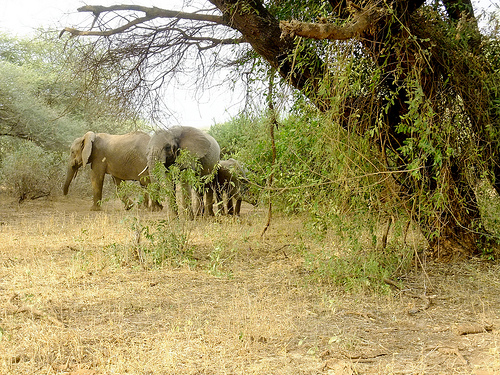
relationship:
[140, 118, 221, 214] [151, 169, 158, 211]
elephant has trunk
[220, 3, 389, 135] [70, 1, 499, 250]
branch of tree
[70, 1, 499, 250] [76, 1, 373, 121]
tree with branches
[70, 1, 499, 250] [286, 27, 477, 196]
tree with leaves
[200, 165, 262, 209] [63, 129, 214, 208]
elephant next to other elephants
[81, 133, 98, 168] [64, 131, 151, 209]
ear of elephant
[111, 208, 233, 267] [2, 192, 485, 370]
stick on ground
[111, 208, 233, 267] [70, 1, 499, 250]
stick by tree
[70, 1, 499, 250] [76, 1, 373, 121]
tree has branches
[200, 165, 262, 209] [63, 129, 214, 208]
elephant with other elephants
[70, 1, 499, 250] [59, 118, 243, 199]
tree near elephants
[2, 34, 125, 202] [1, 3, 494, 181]
tree in background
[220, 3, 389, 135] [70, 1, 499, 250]
branch hanging from tree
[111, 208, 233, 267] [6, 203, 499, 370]
stick laying on grass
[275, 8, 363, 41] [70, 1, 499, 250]
branch hanging from tree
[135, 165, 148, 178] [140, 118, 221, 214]
tusk on elephant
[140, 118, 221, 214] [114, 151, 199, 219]
elephant eating from shrub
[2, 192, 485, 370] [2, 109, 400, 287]
clearing with shrubs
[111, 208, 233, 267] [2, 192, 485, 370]
stick fallen to ground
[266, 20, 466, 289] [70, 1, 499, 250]
vines hanging off tree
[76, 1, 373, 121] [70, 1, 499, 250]
branches on tree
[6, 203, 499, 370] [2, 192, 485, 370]
grass covering ground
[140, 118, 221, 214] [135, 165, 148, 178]
elephant with tusk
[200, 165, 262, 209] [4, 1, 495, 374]
elephant in forest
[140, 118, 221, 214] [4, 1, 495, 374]
elephant in a forest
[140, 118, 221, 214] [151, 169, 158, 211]
elephant with trunk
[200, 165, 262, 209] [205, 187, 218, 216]
elephant has a trunk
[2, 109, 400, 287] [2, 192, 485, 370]
shrubs growing on ground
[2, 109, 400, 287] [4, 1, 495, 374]
shrubs in forest